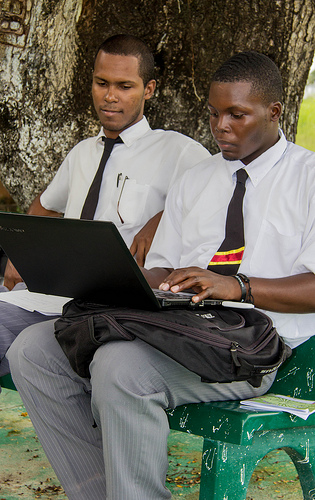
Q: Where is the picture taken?
A: In the park.